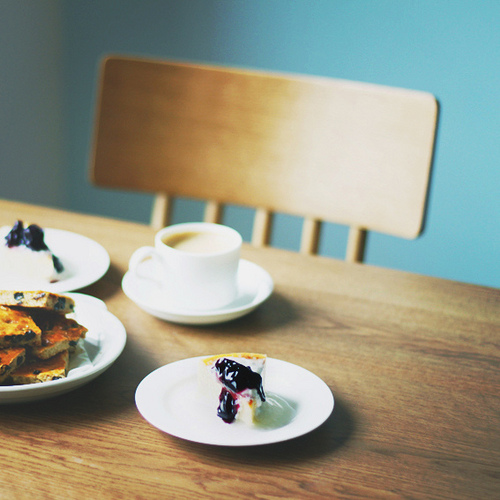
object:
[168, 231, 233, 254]
coffee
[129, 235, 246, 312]
cup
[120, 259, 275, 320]
saucer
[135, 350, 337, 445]
plate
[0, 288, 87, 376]
cookie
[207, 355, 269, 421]
cheesecake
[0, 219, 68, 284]
dessert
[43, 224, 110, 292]
saucer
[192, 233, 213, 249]
creamer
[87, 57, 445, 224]
chair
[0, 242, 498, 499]
table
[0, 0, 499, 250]
wall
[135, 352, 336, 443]
dish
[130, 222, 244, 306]
mug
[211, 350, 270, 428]
food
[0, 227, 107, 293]
plate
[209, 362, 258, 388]
toppings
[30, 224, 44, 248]
sauce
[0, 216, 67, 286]
pie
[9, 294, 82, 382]
squares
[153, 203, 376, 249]
slats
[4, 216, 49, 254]
blackberries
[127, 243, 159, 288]
handle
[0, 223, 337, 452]
plates